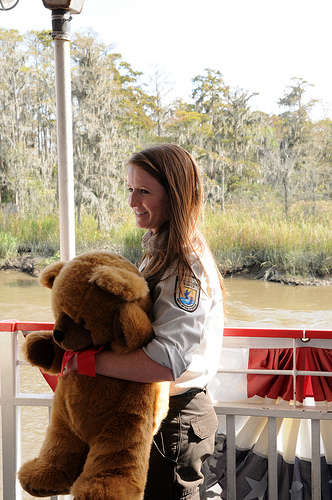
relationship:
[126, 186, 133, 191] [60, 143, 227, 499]
eye of lady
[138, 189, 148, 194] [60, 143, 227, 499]
eye of lady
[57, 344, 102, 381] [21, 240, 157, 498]
bowtie on bear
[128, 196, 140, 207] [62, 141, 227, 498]
nose of woman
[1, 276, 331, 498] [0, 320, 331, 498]
water below railing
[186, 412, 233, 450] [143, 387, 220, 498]
pocket on pants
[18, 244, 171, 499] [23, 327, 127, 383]
bear in woman's hands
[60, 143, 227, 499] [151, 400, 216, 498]
lady wears pants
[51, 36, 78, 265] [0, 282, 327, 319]
white pole in water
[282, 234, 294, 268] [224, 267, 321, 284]
grass on shore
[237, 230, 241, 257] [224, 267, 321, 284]
grass on shore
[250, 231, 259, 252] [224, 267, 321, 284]
grass on shore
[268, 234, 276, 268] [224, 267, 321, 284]
grass on shore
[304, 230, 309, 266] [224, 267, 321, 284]
grass on shore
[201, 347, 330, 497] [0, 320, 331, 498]
flag on railing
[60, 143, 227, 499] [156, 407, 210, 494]
lady wearing pants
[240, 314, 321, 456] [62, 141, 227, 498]
railing behind woman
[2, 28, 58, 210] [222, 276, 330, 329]
trees across water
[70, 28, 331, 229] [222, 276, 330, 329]
trees across water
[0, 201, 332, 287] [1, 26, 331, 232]
grassy area below trees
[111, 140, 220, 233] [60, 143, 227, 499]
head of lady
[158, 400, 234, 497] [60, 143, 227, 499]
pants of lady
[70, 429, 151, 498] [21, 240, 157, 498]
leg of bear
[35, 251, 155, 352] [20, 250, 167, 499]
head of bear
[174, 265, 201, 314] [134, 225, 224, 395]
logo on shirt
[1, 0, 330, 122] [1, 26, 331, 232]
sky above trees